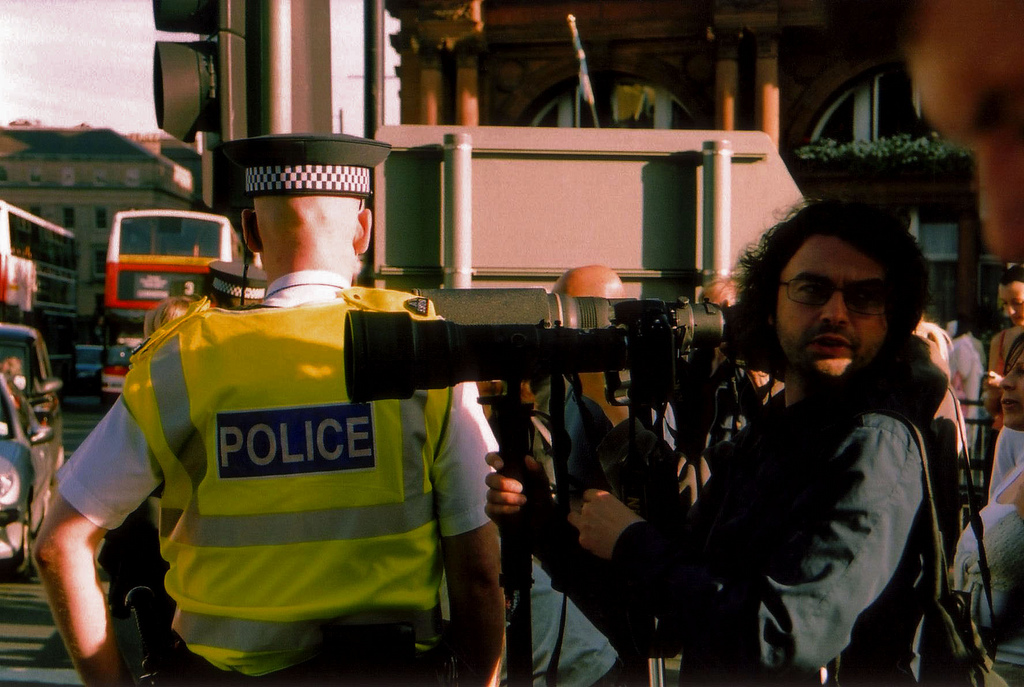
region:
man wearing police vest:
[24, 124, 518, 681]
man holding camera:
[334, 193, 958, 669]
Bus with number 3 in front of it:
[102, 201, 245, 401]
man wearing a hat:
[24, 128, 514, 679]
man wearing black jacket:
[475, 197, 954, 682]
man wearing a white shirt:
[23, 128, 518, 679]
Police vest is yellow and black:
[29, 128, 513, 679]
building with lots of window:
[0, 121, 185, 379]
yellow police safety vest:
[120, 290, 447, 674]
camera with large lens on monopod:
[341, 293, 725, 685]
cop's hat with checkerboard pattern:
[204, 133, 394, 194]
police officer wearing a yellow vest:
[32, 132, 505, 684]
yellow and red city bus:
[106, 209, 258, 323]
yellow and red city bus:
[0, 199, 76, 317]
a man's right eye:
[796, 279, 826, 295]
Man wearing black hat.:
[206, 117, 429, 200]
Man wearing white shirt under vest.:
[47, 288, 484, 624]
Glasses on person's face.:
[789, 268, 936, 327]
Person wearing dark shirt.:
[686, 417, 953, 661]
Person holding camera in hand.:
[379, 241, 730, 618]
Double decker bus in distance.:
[104, 212, 231, 378]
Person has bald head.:
[556, 236, 636, 322]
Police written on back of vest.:
[214, 416, 382, 502]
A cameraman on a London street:
[488, 206, 940, 685]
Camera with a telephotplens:
[342, 299, 735, 490]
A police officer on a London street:
[32, 133, 503, 685]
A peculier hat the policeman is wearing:
[215, 137, 396, 191]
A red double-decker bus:
[104, 204, 240, 398]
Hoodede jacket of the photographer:
[616, 333, 948, 685]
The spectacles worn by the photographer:
[778, 270, 902, 312]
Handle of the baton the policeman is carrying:
[118, 577, 164, 685]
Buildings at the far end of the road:
[1, 122, 195, 399]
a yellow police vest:
[70, 271, 526, 668]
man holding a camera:
[300, 133, 1022, 683]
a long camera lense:
[322, 218, 721, 444]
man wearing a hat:
[174, 104, 416, 209]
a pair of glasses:
[759, 259, 887, 327]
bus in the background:
[47, 174, 238, 352]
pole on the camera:
[525, 351, 678, 624]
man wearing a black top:
[556, 375, 942, 685]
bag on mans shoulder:
[884, 408, 1022, 672]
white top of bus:
[92, 192, 238, 268]